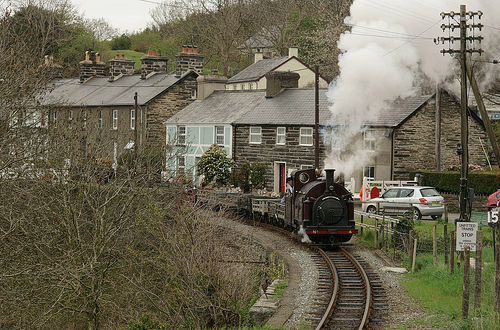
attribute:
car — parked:
[372, 177, 449, 225]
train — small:
[237, 157, 362, 247]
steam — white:
[332, 1, 497, 161]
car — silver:
[354, 177, 445, 243]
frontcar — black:
[283, 165, 360, 242]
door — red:
[268, 160, 290, 192]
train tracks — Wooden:
[321, 251, 371, 313]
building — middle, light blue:
[235, 22, 362, 61]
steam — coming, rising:
[323, 0, 492, 181]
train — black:
[188, 151, 382, 266]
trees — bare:
[15, 53, 195, 310]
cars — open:
[200, 173, 324, 226]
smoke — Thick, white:
[327, 5, 404, 157]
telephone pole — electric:
[438, 2, 486, 227]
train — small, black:
[283, 162, 355, 246]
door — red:
[271, 157, 283, 198]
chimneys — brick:
[39, 43, 205, 76]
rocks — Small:
[294, 253, 319, 309]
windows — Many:
[250, 128, 316, 150]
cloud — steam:
[325, 8, 474, 192]